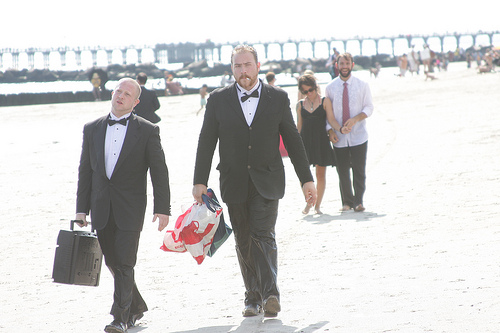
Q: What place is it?
A: It is a beach.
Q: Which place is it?
A: It is a beach.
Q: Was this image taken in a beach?
A: Yes, it was taken in a beach.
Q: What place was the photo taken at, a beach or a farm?
A: It was taken at a beach.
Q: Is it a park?
A: No, it is a beach.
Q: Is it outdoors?
A: Yes, it is outdoors.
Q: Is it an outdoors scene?
A: Yes, it is outdoors.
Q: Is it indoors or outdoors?
A: It is outdoors.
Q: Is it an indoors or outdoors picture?
A: It is outdoors.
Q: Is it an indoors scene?
A: No, it is outdoors.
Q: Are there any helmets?
A: No, there are no helmets.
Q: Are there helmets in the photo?
A: No, there are no helmets.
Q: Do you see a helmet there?
A: No, there are no helmets.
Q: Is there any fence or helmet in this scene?
A: No, there are no helmets or fences.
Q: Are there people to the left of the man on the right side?
A: Yes, there is a person to the left of the man.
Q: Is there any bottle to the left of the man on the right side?
A: No, there is a person to the left of the man.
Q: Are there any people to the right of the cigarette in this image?
A: Yes, there is a person to the right of the cigarette.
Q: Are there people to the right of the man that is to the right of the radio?
A: Yes, there is a person to the right of the man.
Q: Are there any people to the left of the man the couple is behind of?
A: No, the person is to the right of the man.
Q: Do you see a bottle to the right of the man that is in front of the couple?
A: No, there is a person to the right of the man.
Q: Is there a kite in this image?
A: No, there are no kites.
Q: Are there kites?
A: No, there are no kites.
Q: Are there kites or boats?
A: No, there are no kites or boats.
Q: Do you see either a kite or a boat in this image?
A: No, there are no kites or boats.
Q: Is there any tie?
A: Yes, there is a tie.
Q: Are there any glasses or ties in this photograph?
A: Yes, there is a tie.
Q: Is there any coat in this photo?
A: Yes, there is a coat.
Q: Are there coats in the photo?
A: Yes, there is a coat.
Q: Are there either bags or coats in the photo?
A: Yes, there is a coat.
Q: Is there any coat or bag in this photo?
A: Yes, there is a coat.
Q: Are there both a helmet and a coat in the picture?
A: No, there is a coat but no helmets.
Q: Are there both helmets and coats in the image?
A: No, there is a coat but no helmets.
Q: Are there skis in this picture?
A: No, there are no skis.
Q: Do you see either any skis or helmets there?
A: No, there are no skis or helmets.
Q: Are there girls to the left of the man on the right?
A: Yes, there is a girl to the left of the man.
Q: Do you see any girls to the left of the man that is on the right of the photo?
A: Yes, there is a girl to the left of the man.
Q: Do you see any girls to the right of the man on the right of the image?
A: No, the girl is to the left of the man.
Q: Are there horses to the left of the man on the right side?
A: No, there is a girl to the left of the man.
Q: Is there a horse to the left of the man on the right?
A: No, there is a girl to the left of the man.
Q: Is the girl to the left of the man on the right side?
A: Yes, the girl is to the left of the man.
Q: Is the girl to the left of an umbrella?
A: No, the girl is to the left of the man.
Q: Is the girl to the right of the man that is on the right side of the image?
A: No, the girl is to the left of the man.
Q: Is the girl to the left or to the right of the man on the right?
A: The girl is to the left of the man.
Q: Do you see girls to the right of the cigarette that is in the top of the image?
A: Yes, there is a girl to the right of the cigarette.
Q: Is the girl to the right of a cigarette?
A: Yes, the girl is to the right of a cigarette.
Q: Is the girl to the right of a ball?
A: No, the girl is to the right of a cigarette.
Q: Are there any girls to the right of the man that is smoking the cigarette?
A: Yes, there is a girl to the right of the man.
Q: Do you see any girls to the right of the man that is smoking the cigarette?
A: Yes, there is a girl to the right of the man.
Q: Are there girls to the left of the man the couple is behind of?
A: No, the girl is to the right of the man.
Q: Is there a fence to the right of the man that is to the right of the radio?
A: No, there is a girl to the right of the man.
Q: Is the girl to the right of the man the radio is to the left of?
A: Yes, the girl is to the right of the man.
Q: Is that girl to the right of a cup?
A: No, the girl is to the right of the man.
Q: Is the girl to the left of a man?
A: No, the girl is to the right of a man.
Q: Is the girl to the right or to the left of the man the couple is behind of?
A: The girl is to the right of the man.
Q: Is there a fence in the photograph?
A: No, there are no fences.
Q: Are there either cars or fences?
A: No, there are no fences or cars.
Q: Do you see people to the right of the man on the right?
A: Yes, there is a person to the right of the man.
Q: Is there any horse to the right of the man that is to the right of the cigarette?
A: No, there is a person to the right of the man.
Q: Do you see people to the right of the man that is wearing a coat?
A: Yes, there is a person to the right of the man.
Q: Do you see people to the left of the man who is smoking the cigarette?
A: No, the person is to the right of the man.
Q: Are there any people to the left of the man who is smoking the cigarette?
A: No, the person is to the right of the man.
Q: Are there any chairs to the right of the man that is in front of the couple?
A: No, there is a person to the right of the man.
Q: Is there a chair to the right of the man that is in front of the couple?
A: No, there is a person to the right of the man.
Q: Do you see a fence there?
A: No, there are no fences.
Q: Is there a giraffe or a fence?
A: No, there are no fences or giraffes.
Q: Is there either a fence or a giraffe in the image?
A: No, there are no fences or giraffes.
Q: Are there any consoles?
A: No, there are no consoles.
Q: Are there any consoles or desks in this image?
A: No, there are no consoles or desks.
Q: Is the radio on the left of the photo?
A: Yes, the radio is on the left of the image.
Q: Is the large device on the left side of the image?
A: Yes, the radio is on the left of the image.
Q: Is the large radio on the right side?
A: No, the radio is on the left of the image.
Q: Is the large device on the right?
A: No, the radio is on the left of the image.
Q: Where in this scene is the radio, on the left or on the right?
A: The radio is on the left of the image.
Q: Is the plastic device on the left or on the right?
A: The radio is on the left of the image.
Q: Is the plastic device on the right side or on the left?
A: The radio is on the left of the image.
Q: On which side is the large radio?
A: The radio is on the left of the image.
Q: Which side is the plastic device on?
A: The radio is on the left of the image.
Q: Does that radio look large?
A: Yes, the radio is large.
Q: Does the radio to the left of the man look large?
A: Yes, the radio is large.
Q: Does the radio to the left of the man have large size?
A: Yes, the radio is large.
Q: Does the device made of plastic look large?
A: Yes, the radio is large.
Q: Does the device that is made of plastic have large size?
A: Yes, the radio is large.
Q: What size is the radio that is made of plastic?
A: The radio is large.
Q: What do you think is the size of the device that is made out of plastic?
A: The radio is large.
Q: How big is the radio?
A: The radio is large.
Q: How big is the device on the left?
A: The radio is large.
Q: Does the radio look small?
A: No, the radio is large.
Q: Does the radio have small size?
A: No, the radio is large.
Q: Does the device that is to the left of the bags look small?
A: No, the radio is large.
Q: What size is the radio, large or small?
A: The radio is large.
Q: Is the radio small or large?
A: The radio is large.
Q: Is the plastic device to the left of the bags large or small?
A: The radio is large.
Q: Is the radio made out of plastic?
A: Yes, the radio is made of plastic.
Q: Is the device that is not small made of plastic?
A: Yes, the radio is made of plastic.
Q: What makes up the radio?
A: The radio is made of plastic.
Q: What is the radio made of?
A: The radio is made of plastic.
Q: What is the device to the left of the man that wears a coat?
A: The device is a radio.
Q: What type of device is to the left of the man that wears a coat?
A: The device is a radio.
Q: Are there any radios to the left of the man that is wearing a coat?
A: Yes, there is a radio to the left of the man.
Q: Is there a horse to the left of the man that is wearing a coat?
A: No, there is a radio to the left of the man.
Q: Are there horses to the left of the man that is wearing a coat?
A: No, there is a radio to the left of the man.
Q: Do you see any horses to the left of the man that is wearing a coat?
A: No, there is a radio to the left of the man.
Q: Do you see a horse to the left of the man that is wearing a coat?
A: No, there is a radio to the left of the man.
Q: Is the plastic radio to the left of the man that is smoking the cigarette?
A: Yes, the radio is to the left of the man.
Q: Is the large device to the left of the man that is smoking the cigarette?
A: Yes, the radio is to the left of the man.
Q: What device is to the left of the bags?
A: The device is a radio.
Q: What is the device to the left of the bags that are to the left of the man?
A: The device is a radio.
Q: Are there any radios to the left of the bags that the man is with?
A: Yes, there is a radio to the left of the bags.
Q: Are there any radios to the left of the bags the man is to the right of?
A: Yes, there is a radio to the left of the bags.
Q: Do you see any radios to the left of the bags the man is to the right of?
A: Yes, there is a radio to the left of the bags.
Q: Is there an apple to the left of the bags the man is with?
A: No, there is a radio to the left of the bags.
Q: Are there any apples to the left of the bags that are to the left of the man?
A: No, there is a radio to the left of the bags.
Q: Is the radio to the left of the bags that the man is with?
A: Yes, the radio is to the left of the bags.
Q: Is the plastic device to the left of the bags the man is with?
A: Yes, the radio is to the left of the bags.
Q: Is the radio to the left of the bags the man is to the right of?
A: Yes, the radio is to the left of the bags.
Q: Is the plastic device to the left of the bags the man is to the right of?
A: Yes, the radio is to the left of the bags.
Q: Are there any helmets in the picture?
A: No, there are no helmets.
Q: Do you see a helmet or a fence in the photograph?
A: No, there are no helmets or fences.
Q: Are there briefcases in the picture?
A: Yes, there is a briefcase.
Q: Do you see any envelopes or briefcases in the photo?
A: Yes, there is a briefcase.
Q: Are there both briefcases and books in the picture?
A: No, there is a briefcase but no books.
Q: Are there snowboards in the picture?
A: No, there are no snowboards.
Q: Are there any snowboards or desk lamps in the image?
A: No, there are no snowboards or desk lamps.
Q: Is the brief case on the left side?
A: Yes, the brief case is on the left of the image.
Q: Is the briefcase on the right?
A: No, the briefcase is on the left of the image.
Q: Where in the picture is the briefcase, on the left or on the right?
A: The briefcase is on the left of the image.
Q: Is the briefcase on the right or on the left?
A: The briefcase is on the left of the image.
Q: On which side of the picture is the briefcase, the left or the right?
A: The briefcase is on the left of the image.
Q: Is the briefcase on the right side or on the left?
A: The briefcase is on the left of the image.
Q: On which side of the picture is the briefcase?
A: The briefcase is on the left of the image.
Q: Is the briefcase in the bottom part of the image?
A: Yes, the briefcase is in the bottom of the image.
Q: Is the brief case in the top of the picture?
A: No, the brief case is in the bottom of the image.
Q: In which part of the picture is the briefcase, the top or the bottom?
A: The briefcase is in the bottom of the image.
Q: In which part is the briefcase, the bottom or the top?
A: The briefcase is in the bottom of the image.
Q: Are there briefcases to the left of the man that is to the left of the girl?
A: Yes, there is a briefcase to the left of the man.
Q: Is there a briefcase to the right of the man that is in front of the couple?
A: No, the briefcase is to the left of the man.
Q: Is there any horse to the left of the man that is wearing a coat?
A: No, there is a briefcase to the left of the man.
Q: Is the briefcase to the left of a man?
A: Yes, the briefcase is to the left of a man.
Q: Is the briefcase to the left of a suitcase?
A: No, the briefcase is to the left of a man.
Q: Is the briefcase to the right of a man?
A: No, the briefcase is to the left of a man.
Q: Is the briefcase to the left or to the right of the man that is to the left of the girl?
A: The briefcase is to the left of the man.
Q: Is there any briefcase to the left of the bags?
A: Yes, there is a briefcase to the left of the bags.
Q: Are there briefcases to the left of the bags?
A: Yes, there is a briefcase to the left of the bags.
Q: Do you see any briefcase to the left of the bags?
A: Yes, there is a briefcase to the left of the bags.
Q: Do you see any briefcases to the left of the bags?
A: Yes, there is a briefcase to the left of the bags.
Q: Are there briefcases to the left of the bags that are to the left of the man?
A: Yes, there is a briefcase to the left of the bags.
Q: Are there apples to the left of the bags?
A: No, there is a briefcase to the left of the bags.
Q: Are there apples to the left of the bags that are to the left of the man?
A: No, there is a briefcase to the left of the bags.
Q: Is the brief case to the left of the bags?
A: Yes, the brief case is to the left of the bags.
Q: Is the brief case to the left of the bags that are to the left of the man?
A: Yes, the brief case is to the left of the bags.